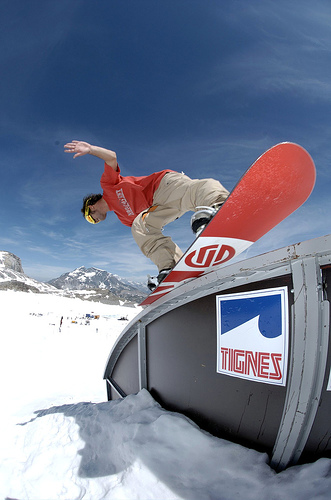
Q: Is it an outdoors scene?
A: Yes, it is outdoors.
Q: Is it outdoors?
A: Yes, it is outdoors.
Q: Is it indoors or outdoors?
A: It is outdoors.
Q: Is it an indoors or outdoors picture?
A: It is outdoors.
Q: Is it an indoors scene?
A: No, it is outdoors.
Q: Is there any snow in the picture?
A: Yes, there is snow.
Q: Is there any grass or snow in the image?
A: Yes, there is snow.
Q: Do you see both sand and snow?
A: No, there is snow but no sand.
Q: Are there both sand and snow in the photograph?
A: No, there is snow but no sand.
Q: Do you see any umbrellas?
A: No, there are no umbrellas.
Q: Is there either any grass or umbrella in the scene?
A: No, there are no umbrellas or grass.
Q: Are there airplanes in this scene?
A: No, there are no airplanes.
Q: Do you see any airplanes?
A: No, there are no airplanes.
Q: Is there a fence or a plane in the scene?
A: No, there are no airplanes or fences.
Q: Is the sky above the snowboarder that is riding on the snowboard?
A: Yes, the sky is above the snowboarder.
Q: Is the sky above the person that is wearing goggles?
A: Yes, the sky is above the snowboarder.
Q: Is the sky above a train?
A: No, the sky is above the snowboarder.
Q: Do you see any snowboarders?
A: Yes, there is a snowboarder.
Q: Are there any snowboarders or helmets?
A: Yes, there is a snowboarder.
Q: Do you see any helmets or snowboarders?
A: Yes, there is a snowboarder.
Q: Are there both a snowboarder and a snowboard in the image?
A: Yes, there are both a snowboarder and a snowboard.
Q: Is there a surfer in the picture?
A: No, there are no surfers.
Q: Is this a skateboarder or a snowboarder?
A: This is a snowboarder.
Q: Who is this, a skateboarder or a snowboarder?
A: This is a snowboarder.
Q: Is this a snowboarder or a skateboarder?
A: This is a snowboarder.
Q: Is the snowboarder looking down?
A: Yes, the snowboarder is looking down.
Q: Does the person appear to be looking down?
A: Yes, the snowboarder is looking down.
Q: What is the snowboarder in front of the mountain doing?
A: The snowboarder is looking down.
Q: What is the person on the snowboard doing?
A: The snowboarder is looking down.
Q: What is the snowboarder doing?
A: The snowboarder is looking down.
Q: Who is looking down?
A: The snowboarder is looking down.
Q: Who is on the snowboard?
A: The snowboarder is on the snowboard.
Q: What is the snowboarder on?
A: The snowboarder is on the snowboard.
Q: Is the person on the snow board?
A: Yes, the snowboarder is on the snow board.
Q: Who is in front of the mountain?
A: The snowboarder is in front of the mountain.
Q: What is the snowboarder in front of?
A: The snowboarder is in front of the mountain.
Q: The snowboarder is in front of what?
A: The snowboarder is in front of the mountain.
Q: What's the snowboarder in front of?
A: The snowboarder is in front of the mountain.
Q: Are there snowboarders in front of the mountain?
A: Yes, there is a snowboarder in front of the mountain.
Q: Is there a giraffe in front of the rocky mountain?
A: No, there is a snowboarder in front of the mountain.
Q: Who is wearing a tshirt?
A: The snowboarder is wearing a tshirt.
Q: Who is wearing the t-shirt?
A: The snowboarder is wearing a tshirt.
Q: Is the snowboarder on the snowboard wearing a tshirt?
A: Yes, the snowboarder is wearing a tshirt.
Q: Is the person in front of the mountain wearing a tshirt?
A: Yes, the snowboarder is wearing a tshirt.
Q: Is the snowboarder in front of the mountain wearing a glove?
A: No, the snowboarder is wearing a tshirt.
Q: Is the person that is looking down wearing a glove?
A: No, the snowboarder is wearing a tshirt.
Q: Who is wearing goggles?
A: The snowboarder is wearing goggles.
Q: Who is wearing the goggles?
A: The snowboarder is wearing goggles.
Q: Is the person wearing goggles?
A: Yes, the snowboarder is wearing goggles.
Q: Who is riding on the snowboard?
A: The snowboarder is riding on the snowboard.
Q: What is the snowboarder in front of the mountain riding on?
A: The snowboarder is riding on the snowboard.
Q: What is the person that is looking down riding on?
A: The snowboarder is riding on the snowboard.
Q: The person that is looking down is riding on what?
A: The snowboarder is riding on the snowboard.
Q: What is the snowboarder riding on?
A: The snowboarder is riding on the snowboard.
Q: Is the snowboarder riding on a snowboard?
A: Yes, the snowboarder is riding on a snowboard.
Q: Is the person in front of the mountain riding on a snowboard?
A: Yes, the snowboarder is riding on a snowboard.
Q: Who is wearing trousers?
A: The snowboarder is wearing trousers.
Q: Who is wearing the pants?
A: The snowboarder is wearing trousers.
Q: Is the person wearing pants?
A: Yes, the snowboarder is wearing pants.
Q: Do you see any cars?
A: No, there are no cars.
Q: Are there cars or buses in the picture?
A: No, there are no cars or buses.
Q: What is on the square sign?
A: The word is on the sign.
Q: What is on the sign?
A: The word is on the sign.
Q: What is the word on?
A: The word is on the sign.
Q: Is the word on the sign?
A: Yes, the word is on the sign.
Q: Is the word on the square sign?
A: Yes, the word is on the sign.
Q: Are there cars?
A: No, there are no cars.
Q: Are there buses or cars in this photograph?
A: No, there are no cars or buses.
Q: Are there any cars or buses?
A: No, there are no cars or buses.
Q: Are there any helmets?
A: No, there are no helmets.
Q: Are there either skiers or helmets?
A: No, there are no helmets or skiers.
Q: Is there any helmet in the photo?
A: No, there are no helmets.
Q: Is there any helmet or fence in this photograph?
A: No, there are no helmets or fences.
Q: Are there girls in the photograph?
A: No, there are no girls.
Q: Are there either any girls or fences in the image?
A: No, there are no girls or fences.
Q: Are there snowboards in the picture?
A: Yes, there is a snowboard.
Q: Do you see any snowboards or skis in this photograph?
A: Yes, there is a snowboard.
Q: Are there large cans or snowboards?
A: Yes, there is a large snowboard.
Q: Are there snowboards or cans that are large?
A: Yes, the snowboard is large.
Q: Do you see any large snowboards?
A: Yes, there is a large snowboard.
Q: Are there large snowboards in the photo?
A: Yes, there is a large snowboard.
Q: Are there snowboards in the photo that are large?
A: Yes, there is a snowboard that is large.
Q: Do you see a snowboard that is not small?
A: Yes, there is a large snowboard.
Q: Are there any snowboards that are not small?
A: Yes, there is a large snowboard.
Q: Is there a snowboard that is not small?
A: Yes, there is a large snowboard.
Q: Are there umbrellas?
A: No, there are no umbrellas.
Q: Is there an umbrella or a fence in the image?
A: No, there are no umbrellas or fences.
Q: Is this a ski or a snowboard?
A: This is a snowboard.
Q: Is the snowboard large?
A: Yes, the snowboard is large.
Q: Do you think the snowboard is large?
A: Yes, the snowboard is large.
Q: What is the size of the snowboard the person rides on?
A: The snowboard is large.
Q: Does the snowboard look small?
A: No, the snowboard is large.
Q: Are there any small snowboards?
A: No, there is a snowboard but it is large.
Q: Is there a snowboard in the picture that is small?
A: No, there is a snowboard but it is large.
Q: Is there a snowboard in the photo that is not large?
A: No, there is a snowboard but it is large.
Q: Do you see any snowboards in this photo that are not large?
A: No, there is a snowboard but it is large.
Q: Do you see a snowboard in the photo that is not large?
A: No, there is a snowboard but it is large.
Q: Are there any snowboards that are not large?
A: No, there is a snowboard but it is large.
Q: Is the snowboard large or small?
A: The snowboard is large.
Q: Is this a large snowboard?
A: Yes, this is a large snowboard.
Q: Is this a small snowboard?
A: No, this is a large snowboard.